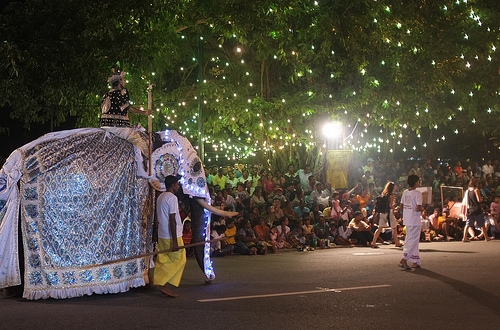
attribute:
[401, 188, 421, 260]
dress — white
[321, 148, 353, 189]
sign — yellow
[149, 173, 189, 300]
man — barefoot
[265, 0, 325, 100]
branch — big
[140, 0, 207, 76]
branch — big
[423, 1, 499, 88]
branch — big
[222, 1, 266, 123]
branch — big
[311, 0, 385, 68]
branch — big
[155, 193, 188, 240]
shirt — white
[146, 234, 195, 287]
bottoms — yellow